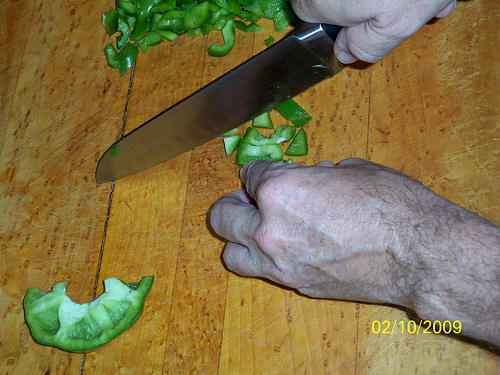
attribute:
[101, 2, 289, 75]
paprika — green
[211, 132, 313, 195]
paprica — green 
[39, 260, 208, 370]
paprica — green 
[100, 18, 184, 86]
paprica — green 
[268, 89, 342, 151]
paprica — green 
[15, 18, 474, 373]
board — brown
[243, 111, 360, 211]
peppers — green 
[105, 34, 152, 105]
peppers — green 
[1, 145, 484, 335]
table — cutting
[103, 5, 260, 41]
cuts — Many 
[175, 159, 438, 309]
hand — man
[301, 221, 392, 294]
veins — popping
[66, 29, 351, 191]
knife — big, silver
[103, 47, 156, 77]
papricca — green, piece 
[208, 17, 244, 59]
papricca — piece , green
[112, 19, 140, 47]
papricca — green,  piece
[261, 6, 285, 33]
papricca —  piece,  green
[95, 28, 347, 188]
knife — silver , long , being held, metal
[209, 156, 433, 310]
hand — holding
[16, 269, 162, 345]
pepper — piece, green, cut, bell 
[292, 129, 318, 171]
pepper — bell ,  cut , piece 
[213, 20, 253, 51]
pepper — piece , cut,  green, bell 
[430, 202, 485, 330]
arm —  left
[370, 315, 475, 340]
stamp — date 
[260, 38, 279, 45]
pepper — piece, cut, green,  bell 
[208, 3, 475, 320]
hands —  cutting 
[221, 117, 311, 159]
pepper —  bell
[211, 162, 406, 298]
hand —  holding 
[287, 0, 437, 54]
hand —  holding 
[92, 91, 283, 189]
blade — Silver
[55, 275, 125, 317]
membrane — White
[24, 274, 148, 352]
pepper — slice, green, cut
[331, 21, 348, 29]
handle — BLACK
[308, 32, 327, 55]
trim — SILVER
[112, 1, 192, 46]
pepper — CHOPPED, BELL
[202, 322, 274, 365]
block — CHOPPING, BROWN, LIGHT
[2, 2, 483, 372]
chopping board — wooden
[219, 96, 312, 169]
pepper — green, cut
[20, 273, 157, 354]
pepper — green, getting cut, cut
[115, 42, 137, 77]
pepper — cut, green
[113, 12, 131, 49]
pepper — cut, green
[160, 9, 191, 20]
pepper — cut, green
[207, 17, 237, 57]
pepper — cut, green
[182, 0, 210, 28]
pepper — cut, green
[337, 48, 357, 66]
nail — white